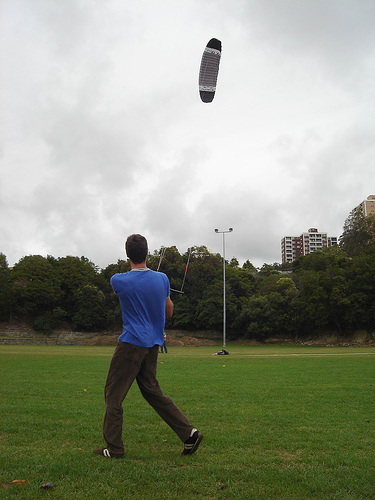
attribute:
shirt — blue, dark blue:
[108, 267, 172, 350]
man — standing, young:
[95, 233, 204, 460]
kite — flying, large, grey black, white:
[198, 36, 223, 105]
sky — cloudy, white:
[2, 0, 374, 269]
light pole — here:
[215, 227, 236, 356]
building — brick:
[280, 227, 339, 269]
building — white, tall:
[356, 193, 374, 229]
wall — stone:
[1, 325, 113, 346]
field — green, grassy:
[2, 344, 375, 499]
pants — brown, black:
[101, 339, 195, 455]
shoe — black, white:
[179, 430, 202, 458]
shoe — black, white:
[92, 447, 126, 460]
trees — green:
[0, 201, 374, 339]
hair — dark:
[126, 233, 149, 265]